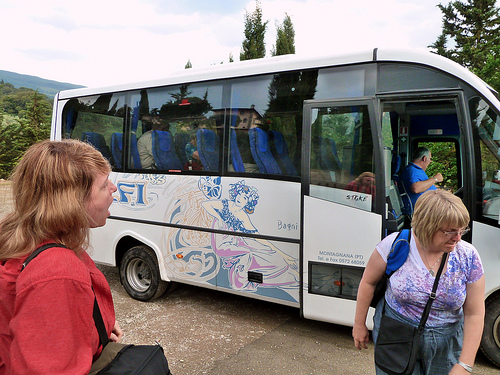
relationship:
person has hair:
[9, 132, 122, 375] [8, 131, 102, 254]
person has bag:
[9, 132, 122, 375] [85, 336, 178, 373]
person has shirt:
[9, 132, 122, 375] [7, 235, 114, 374]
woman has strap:
[337, 184, 487, 367] [378, 229, 414, 276]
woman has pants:
[337, 184, 487, 367] [361, 311, 470, 370]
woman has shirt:
[337, 184, 487, 367] [374, 232, 486, 322]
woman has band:
[337, 184, 487, 367] [456, 357, 472, 372]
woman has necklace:
[337, 184, 487, 367] [420, 249, 444, 280]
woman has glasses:
[337, 184, 487, 367] [435, 222, 474, 240]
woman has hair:
[337, 184, 487, 367] [407, 179, 473, 234]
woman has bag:
[337, 184, 487, 367] [375, 308, 423, 370]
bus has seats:
[40, 37, 489, 328] [246, 127, 294, 175]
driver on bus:
[398, 143, 444, 190] [40, 37, 489, 328]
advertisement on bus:
[161, 172, 299, 302] [40, 37, 489, 328]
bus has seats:
[40, 37, 489, 328] [85, 132, 139, 162]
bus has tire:
[40, 37, 489, 328] [119, 242, 173, 298]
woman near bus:
[337, 184, 487, 367] [40, 37, 489, 328]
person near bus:
[9, 132, 122, 375] [40, 37, 489, 328]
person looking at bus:
[9, 132, 122, 375] [40, 37, 489, 328]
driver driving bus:
[398, 143, 444, 190] [40, 37, 489, 328]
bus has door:
[40, 37, 489, 328] [297, 93, 483, 347]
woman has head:
[337, 184, 487, 367] [405, 179, 472, 256]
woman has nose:
[337, 184, 487, 367] [454, 235, 464, 245]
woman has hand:
[337, 184, 487, 367] [350, 320, 372, 350]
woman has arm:
[337, 184, 487, 367] [345, 247, 391, 322]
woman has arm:
[337, 184, 487, 367] [463, 279, 489, 367]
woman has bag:
[337, 184, 487, 367] [85, 336, 178, 373]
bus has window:
[40, 37, 489, 328] [228, 71, 315, 184]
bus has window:
[40, 37, 489, 328] [121, 77, 230, 166]